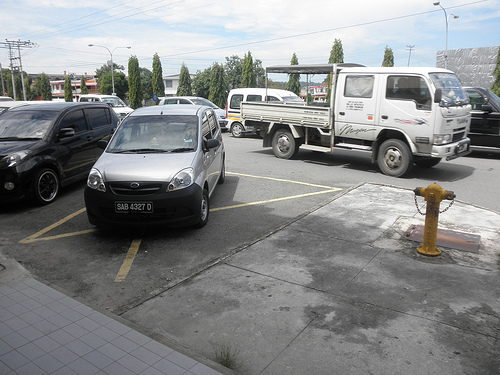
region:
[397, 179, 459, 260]
a yellow fire hydrant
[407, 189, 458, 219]
a chain on the yellow fire hydrant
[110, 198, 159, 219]
the license plate on the front of the car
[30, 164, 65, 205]
the front left tire of the black car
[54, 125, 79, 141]
the left mirror of the black car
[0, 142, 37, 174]
the left headlight of the black car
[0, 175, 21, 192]
the left fog light of the black car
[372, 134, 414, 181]
the front right tire of the truck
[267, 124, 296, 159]
the back right tire of the truck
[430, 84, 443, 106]
the right mirror of the truck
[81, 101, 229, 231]
a parked silver car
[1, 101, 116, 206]
a parked black car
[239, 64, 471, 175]
a white tow truck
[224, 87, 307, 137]
a parked white van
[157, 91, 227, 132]
a parked silver car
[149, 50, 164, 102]
a tal thin tree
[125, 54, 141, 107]
a tal thin tree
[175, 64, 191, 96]
a tal thin tree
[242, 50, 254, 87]
a tal thin tree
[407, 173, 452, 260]
yellow fire hydrant in park lot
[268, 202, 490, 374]
wet marks on pavement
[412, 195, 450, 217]
chains hanging from yellow fire hydrant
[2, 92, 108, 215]
black car in parking lot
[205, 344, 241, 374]
weed growing through crack in pavement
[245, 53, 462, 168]
flat bed truck driving through parking lot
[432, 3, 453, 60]
street light in background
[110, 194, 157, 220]
front licence plate of car parked on yellow markings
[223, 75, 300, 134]
white van behind truck bed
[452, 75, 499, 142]
black suv beside flat bed truck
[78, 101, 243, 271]
a vehicle parked on yellow lines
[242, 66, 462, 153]
a white truck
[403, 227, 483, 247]
a metal access panel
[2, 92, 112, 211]
a black vehicle in parked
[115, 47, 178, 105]
two tall green trees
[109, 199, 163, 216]
a black tag with white numbers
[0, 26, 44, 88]
a metal electrical pole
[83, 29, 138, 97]
a tall street light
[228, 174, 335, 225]
yellow lines painted on pavement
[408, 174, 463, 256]
a yellow hydrant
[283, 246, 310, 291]
part of a floor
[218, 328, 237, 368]
part of a glass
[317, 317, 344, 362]
part fo a floor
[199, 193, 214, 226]
part of a wheel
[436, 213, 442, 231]
aprt of a chan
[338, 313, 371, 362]
part of a floor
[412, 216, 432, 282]
[part of a tank